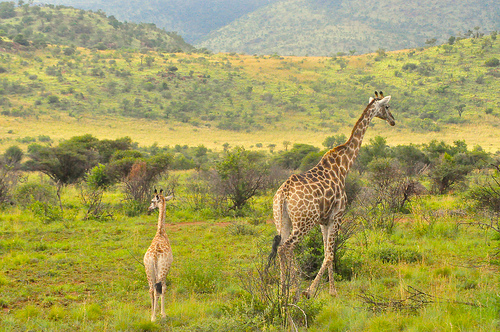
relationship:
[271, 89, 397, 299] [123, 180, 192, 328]
adult giraffe behind giraffe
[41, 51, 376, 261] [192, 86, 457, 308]
trees are behind giraffes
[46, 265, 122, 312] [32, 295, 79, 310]
grass covering ground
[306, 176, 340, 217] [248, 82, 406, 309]
spots on giraffe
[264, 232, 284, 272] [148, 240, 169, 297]
black hair at end of tail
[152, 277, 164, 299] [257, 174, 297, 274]
black hair at end of tail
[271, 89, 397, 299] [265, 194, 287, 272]
adult giraffe has tail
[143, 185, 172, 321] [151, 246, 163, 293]
giraffe has tail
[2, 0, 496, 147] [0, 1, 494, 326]
hills with grass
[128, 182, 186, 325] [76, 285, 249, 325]
giraffe in grass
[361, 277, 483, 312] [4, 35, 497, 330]
branch on ground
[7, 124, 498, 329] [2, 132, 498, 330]
land with vegetation